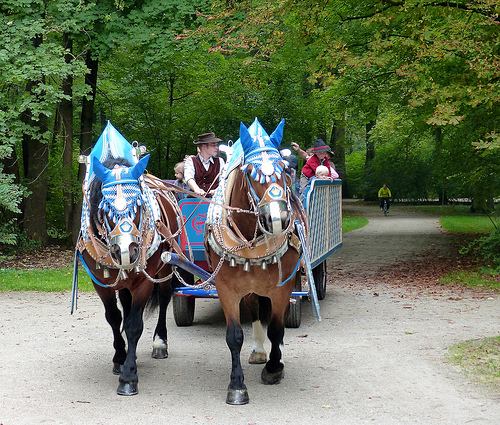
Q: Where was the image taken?
A: It was taken at the path.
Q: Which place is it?
A: It is a path.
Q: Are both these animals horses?
A: Yes, all the animals are horses.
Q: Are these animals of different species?
A: No, all the animals are horses.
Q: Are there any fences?
A: No, there are no fences.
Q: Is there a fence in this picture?
A: No, there are no fences.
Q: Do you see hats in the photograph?
A: Yes, there is a hat.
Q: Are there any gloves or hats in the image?
A: Yes, there is a hat.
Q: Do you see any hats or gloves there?
A: Yes, there is a hat.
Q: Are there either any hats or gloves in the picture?
A: Yes, there is a hat.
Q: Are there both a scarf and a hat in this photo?
A: No, there is a hat but no scarves.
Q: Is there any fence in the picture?
A: No, there are no fences.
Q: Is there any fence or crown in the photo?
A: No, there are no fences or crowns.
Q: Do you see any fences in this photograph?
A: No, there are no fences.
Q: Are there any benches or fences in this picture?
A: No, there are no fences or benches.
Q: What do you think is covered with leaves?
A: The path is covered with leaves.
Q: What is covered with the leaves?
A: The path is covered with leaves.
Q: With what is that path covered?
A: The path is covered with leaves.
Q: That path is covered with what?
A: The path is covered with leaves.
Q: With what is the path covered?
A: The path is covered with leaves.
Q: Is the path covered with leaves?
A: Yes, the path is covered with leaves.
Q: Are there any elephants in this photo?
A: No, there are no elephants.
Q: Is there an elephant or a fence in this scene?
A: No, there are no elephants or fences.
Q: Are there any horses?
A: Yes, there is a horse.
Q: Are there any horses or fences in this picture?
A: Yes, there is a horse.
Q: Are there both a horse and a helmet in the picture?
A: No, there is a horse but no helmets.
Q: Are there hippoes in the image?
A: No, there are no hippoes.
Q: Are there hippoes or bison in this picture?
A: No, there are no hippoes or bison.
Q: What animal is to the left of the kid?
A: The animal is a horse.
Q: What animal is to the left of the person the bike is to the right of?
A: The animal is a horse.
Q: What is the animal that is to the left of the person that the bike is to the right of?
A: The animal is a horse.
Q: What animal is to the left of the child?
A: The animal is a horse.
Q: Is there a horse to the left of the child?
A: Yes, there is a horse to the left of the child.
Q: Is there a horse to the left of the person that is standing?
A: Yes, there is a horse to the left of the child.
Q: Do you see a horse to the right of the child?
A: No, the horse is to the left of the child.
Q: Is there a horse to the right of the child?
A: No, the horse is to the left of the child.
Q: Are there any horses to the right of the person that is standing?
A: No, the horse is to the left of the child.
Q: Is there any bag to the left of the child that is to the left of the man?
A: No, there is a horse to the left of the child.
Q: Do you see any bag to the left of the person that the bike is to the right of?
A: No, there is a horse to the left of the child.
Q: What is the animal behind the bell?
A: The animal is a horse.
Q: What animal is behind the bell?
A: The animal is a horse.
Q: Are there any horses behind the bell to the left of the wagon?
A: Yes, there is a horse behind the bell.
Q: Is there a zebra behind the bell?
A: No, there is a horse behind the bell.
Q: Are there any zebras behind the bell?
A: No, there is a horse behind the bell.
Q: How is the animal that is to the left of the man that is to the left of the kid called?
A: The animal is a horse.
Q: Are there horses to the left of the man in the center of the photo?
A: Yes, there is a horse to the left of the man.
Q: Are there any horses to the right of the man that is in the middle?
A: No, the horse is to the left of the man.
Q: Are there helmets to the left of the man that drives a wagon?
A: No, there is a horse to the left of the man.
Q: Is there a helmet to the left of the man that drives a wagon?
A: No, there is a horse to the left of the man.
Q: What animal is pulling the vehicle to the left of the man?
A: The horse is pulling the wagon.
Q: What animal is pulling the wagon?
A: The horse is pulling the wagon.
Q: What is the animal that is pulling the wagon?
A: The animal is a horse.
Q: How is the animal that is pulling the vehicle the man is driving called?
A: The animal is a horse.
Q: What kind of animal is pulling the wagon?
A: The animal is a horse.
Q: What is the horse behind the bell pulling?
A: The horse is pulling the wagon.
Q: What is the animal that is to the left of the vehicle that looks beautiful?
A: The animal is a horse.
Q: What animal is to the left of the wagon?
A: The animal is a horse.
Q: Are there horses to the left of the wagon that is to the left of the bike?
A: Yes, there is a horse to the left of the wagon.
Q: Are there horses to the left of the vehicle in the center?
A: Yes, there is a horse to the left of the wagon.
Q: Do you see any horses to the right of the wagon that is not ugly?
A: No, the horse is to the left of the wagon.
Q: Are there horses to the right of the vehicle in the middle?
A: No, the horse is to the left of the wagon.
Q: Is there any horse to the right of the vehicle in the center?
A: No, the horse is to the left of the wagon.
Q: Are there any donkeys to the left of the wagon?
A: No, there is a horse to the left of the wagon.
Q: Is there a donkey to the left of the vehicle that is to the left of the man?
A: No, there is a horse to the left of the wagon.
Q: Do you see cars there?
A: No, there are no cars.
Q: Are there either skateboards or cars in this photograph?
A: No, there are no cars or skateboards.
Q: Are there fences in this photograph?
A: No, there are no fences.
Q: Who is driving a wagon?
A: The man is driving a wagon.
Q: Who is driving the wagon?
A: The man is driving a wagon.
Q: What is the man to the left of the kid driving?
A: The man is driving a wagon.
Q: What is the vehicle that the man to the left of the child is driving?
A: The vehicle is a wagon.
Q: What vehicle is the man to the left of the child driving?
A: The man is driving a wagon.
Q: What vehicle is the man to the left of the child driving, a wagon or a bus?
A: The man is driving a wagon.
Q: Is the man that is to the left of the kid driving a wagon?
A: Yes, the man is driving a wagon.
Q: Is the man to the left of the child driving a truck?
A: No, the man is driving a wagon.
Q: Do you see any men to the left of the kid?
A: Yes, there is a man to the left of the kid.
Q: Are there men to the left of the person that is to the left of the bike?
A: Yes, there is a man to the left of the kid.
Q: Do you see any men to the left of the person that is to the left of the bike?
A: Yes, there is a man to the left of the kid.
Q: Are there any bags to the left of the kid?
A: No, there is a man to the left of the kid.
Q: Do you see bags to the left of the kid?
A: No, there is a man to the left of the kid.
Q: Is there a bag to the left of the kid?
A: No, there is a man to the left of the kid.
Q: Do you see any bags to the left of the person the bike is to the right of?
A: No, there is a man to the left of the kid.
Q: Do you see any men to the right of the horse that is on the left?
A: Yes, there is a man to the right of the horse.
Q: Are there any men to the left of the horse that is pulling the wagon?
A: No, the man is to the right of the horse.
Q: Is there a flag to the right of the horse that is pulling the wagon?
A: No, there is a man to the right of the horse.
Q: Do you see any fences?
A: No, there are no fences.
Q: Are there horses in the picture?
A: Yes, there is a horse.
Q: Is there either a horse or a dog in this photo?
A: Yes, there is a horse.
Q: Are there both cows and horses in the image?
A: No, there is a horse but no cows.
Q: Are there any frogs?
A: No, there are no frogs.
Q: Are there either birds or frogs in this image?
A: No, there are no frogs or birds.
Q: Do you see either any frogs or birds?
A: No, there are no frogs or birds.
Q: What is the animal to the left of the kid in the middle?
A: The animal is a horse.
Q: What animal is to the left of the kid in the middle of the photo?
A: The animal is a horse.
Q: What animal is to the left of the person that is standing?
A: The animal is a horse.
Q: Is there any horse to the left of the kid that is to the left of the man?
A: Yes, there is a horse to the left of the child.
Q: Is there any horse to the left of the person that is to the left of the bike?
A: Yes, there is a horse to the left of the child.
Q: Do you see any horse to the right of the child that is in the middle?
A: No, the horse is to the left of the kid.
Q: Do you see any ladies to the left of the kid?
A: No, there is a horse to the left of the kid.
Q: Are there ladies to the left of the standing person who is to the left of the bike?
A: No, there is a horse to the left of the kid.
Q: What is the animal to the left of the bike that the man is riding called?
A: The animal is a horse.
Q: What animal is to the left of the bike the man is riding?
A: The animal is a horse.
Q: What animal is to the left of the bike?
A: The animal is a horse.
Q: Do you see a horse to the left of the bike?
A: Yes, there is a horse to the left of the bike.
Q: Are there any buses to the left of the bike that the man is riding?
A: No, there is a horse to the left of the bike.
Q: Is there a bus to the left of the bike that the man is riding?
A: No, there is a horse to the left of the bike.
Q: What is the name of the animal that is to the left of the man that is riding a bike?
A: The animal is a horse.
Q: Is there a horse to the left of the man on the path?
A: Yes, there is a horse to the left of the man.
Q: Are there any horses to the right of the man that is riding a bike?
A: No, the horse is to the left of the man.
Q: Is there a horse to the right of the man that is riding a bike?
A: No, the horse is to the left of the man.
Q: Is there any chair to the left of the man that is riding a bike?
A: No, there is a horse to the left of the man.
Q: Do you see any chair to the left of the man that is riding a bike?
A: No, there is a horse to the left of the man.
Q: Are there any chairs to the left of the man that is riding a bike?
A: No, there is a horse to the left of the man.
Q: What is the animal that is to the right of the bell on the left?
A: The animal is a horse.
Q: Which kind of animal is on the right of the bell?
A: The animal is a horse.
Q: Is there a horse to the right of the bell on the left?
A: Yes, there is a horse to the right of the bell.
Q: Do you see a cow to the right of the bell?
A: No, there is a horse to the right of the bell.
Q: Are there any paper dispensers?
A: No, there are no paper dispensers.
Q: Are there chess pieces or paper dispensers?
A: No, there are no paper dispensers or chess pieces.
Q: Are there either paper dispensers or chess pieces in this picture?
A: No, there are no paper dispensers or chess pieces.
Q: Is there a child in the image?
A: Yes, there is a child.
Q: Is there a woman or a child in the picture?
A: Yes, there is a child.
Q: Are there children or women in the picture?
A: Yes, there is a child.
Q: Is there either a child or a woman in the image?
A: Yes, there is a child.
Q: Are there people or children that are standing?
A: Yes, the child is standing.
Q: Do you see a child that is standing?
A: Yes, there is a child that is standing.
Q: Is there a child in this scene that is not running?
A: Yes, there is a child that is standing.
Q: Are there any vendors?
A: No, there are no vendors.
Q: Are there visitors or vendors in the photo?
A: No, there are no vendors or visitors.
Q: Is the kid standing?
A: Yes, the kid is standing.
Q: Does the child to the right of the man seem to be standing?
A: Yes, the child is standing.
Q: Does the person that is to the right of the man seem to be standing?
A: Yes, the child is standing.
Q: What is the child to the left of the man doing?
A: The child is standing.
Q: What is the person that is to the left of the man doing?
A: The child is standing.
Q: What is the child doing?
A: The child is standing.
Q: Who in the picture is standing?
A: The kid is standing.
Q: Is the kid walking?
A: No, the kid is standing.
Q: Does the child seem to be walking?
A: No, the child is standing.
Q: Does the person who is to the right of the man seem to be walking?
A: No, the child is standing.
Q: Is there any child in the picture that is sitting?
A: No, there is a child but he is standing.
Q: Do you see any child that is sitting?
A: No, there is a child but he is standing.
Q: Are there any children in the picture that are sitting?
A: No, there is a child but he is standing.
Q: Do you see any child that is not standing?
A: No, there is a child but he is standing.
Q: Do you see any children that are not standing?
A: No, there is a child but he is standing.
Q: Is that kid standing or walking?
A: The kid is standing.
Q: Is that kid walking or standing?
A: The kid is standing.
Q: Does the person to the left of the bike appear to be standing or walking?
A: The kid is standing.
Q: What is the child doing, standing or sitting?
A: The child is standing.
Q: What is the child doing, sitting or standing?
A: The child is standing.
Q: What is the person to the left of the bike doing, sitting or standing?
A: The child is standing.